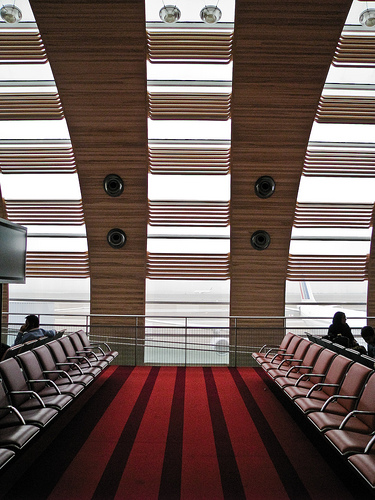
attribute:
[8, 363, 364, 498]
carpet — red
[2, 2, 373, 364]
wall — large, wood, glass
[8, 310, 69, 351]
person — pictured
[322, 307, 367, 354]
person — pictured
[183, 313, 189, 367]
pole — pictured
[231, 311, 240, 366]
pole — pictured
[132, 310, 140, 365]
pole — pictured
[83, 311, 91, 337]
pole — pictured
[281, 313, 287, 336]
pole — pictured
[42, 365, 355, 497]
carpet — red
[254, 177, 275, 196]
object — round, black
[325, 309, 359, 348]
person — pictured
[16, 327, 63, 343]
shirt — light blue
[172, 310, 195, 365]
pole — pictured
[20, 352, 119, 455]
seats — red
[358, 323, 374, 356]
person — pictured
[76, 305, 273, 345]
pole — pictured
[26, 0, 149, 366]
wood — round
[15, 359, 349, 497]
seats — red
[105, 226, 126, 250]
object — black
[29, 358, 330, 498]
stripes — dark red